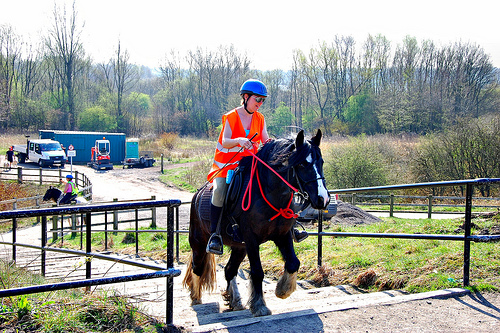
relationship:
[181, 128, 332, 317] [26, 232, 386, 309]
horse walking stairs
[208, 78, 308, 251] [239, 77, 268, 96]
person wearing helmet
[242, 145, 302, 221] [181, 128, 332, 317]
reigns on horse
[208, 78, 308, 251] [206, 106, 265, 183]
person wearing construction jacket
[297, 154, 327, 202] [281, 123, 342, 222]
patch on face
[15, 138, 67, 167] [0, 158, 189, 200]
white truck on dirt road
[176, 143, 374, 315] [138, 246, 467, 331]
horse moving staircase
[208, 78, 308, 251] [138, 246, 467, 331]
person moving staircase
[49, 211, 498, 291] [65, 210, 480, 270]
fenced area protecting grass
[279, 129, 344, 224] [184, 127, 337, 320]
head on horse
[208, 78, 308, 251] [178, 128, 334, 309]
person on horse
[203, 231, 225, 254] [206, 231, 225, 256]
shoe worn foot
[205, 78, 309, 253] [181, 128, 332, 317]
person riding horse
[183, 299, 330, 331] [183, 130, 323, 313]
shadow of a horse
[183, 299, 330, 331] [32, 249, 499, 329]
shadow on steps